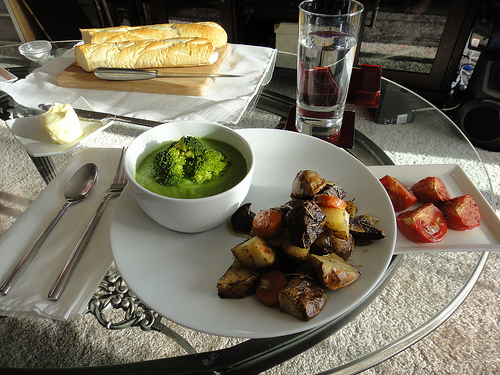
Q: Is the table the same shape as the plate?
A: Yes, both the table and the plate are round.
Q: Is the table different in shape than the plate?
A: No, both the table and the plate are round.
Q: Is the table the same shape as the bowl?
A: Yes, both the table and the bowl are round.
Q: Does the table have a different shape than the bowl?
A: No, both the table and the bowl are round.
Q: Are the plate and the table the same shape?
A: Yes, both the plate and the table are round.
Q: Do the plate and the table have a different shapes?
A: No, both the plate and the table are round.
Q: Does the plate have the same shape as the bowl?
A: Yes, both the plate and the bowl are round.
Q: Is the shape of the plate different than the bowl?
A: No, both the plate and the bowl are round.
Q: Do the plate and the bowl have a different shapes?
A: No, both the plate and the bowl are round.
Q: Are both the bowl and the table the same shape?
A: Yes, both the bowl and the table are round.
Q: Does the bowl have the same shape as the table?
A: Yes, both the bowl and the table are round.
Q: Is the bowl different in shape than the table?
A: No, both the bowl and the table are round.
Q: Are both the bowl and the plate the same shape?
A: Yes, both the bowl and the plate are round.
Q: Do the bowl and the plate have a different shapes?
A: No, both the bowl and the plate are round.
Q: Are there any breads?
A: Yes, there is a bread.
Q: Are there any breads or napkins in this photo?
A: Yes, there is a bread.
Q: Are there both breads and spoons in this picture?
A: Yes, there are both a bread and a spoon.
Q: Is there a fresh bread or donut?
A: Yes, there is a fresh bread.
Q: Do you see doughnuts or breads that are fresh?
A: Yes, the bread is fresh.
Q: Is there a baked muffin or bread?
A: Yes, there is a baked bread.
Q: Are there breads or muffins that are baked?
A: Yes, the bread is baked.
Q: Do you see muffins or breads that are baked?
A: Yes, the bread is baked.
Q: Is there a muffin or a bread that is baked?
A: Yes, the bread is baked.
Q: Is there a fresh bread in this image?
A: Yes, there is a fresh bread.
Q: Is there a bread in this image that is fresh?
A: Yes, there is a bread that is fresh.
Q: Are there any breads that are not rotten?
A: Yes, there is a fresh bread.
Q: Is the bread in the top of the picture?
A: Yes, the bread is in the top of the image.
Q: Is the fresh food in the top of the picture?
A: Yes, the bread is in the top of the image.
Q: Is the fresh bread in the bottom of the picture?
A: No, the bread is in the top of the image.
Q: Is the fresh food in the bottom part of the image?
A: No, the bread is in the top of the image.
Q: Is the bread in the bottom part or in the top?
A: The bread is in the top of the image.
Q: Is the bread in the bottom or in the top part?
A: The bread is in the top of the image.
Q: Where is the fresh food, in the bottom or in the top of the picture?
A: The bread is in the top of the image.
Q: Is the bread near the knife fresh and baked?
A: Yes, the bread is fresh and baked.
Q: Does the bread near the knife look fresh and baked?
A: Yes, the bread is fresh and baked.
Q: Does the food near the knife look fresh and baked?
A: Yes, the bread is fresh and baked.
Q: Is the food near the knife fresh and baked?
A: Yes, the bread is fresh and baked.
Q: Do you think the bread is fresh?
A: Yes, the bread is fresh.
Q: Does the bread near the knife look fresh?
A: Yes, the bread is fresh.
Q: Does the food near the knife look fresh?
A: Yes, the bread is fresh.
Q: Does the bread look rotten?
A: No, the bread is fresh.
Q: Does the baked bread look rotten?
A: No, the bread is fresh.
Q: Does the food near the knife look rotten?
A: No, the bread is fresh.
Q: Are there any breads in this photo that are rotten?
A: No, there is a bread but it is fresh.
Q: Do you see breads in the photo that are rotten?
A: No, there is a bread but it is fresh.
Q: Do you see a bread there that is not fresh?
A: No, there is a bread but it is fresh.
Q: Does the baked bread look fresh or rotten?
A: The bread is fresh.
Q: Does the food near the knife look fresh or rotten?
A: The bread is fresh.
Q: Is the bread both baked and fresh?
A: Yes, the bread is baked and fresh.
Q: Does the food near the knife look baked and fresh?
A: Yes, the bread is baked and fresh.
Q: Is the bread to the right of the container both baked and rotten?
A: No, the bread is baked but fresh.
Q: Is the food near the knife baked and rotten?
A: No, the bread is baked but fresh.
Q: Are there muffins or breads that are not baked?
A: No, there is a bread but it is baked.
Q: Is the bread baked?
A: Yes, the bread is baked.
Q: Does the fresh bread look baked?
A: Yes, the bread is baked.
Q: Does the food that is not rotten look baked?
A: Yes, the bread is baked.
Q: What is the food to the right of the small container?
A: The food is a bread.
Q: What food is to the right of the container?
A: The food is a bread.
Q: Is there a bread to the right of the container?
A: Yes, there is a bread to the right of the container.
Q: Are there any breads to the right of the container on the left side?
A: Yes, there is a bread to the right of the container.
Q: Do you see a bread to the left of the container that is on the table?
A: No, the bread is to the right of the container.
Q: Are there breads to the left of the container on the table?
A: No, the bread is to the right of the container.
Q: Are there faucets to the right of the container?
A: No, there is a bread to the right of the container.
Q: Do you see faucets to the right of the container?
A: No, there is a bread to the right of the container.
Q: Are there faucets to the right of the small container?
A: No, there is a bread to the right of the container.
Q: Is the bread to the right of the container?
A: Yes, the bread is to the right of the container.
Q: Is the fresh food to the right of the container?
A: Yes, the bread is to the right of the container.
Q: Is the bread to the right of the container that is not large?
A: Yes, the bread is to the right of the container.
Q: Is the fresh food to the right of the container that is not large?
A: Yes, the bread is to the right of the container.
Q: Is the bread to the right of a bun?
A: No, the bread is to the right of the container.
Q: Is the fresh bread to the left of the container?
A: No, the bread is to the right of the container.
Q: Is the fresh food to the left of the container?
A: No, the bread is to the right of the container.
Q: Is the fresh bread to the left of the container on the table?
A: No, the bread is to the right of the container.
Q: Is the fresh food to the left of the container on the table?
A: No, the bread is to the right of the container.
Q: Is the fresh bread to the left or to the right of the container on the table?
A: The bread is to the right of the container.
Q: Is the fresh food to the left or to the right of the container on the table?
A: The bread is to the right of the container.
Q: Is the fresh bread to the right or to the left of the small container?
A: The bread is to the right of the container.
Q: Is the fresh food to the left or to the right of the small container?
A: The bread is to the right of the container.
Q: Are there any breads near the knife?
A: Yes, there is a bread near the knife.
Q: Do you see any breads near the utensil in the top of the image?
A: Yes, there is a bread near the knife.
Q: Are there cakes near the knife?
A: No, there is a bread near the knife.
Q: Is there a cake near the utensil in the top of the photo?
A: No, there is a bread near the knife.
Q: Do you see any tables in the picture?
A: Yes, there is a table.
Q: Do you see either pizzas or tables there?
A: Yes, there is a table.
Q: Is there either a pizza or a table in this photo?
A: Yes, there is a table.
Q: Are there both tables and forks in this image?
A: Yes, there are both a table and a fork.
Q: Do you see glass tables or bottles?
A: Yes, there is a glass table.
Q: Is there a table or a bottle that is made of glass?
A: Yes, the table is made of glass.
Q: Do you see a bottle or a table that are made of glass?
A: Yes, the table is made of glass.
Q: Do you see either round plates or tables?
A: Yes, there is a round table.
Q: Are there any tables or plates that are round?
A: Yes, the table is round.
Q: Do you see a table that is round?
A: Yes, there is a round table.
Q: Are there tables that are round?
A: Yes, there is a table that is round.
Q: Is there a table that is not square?
A: Yes, there is a round table.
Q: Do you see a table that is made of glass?
A: Yes, there is a table that is made of glass.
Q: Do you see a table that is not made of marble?
A: Yes, there is a table that is made of glass.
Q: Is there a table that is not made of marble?
A: Yes, there is a table that is made of glass.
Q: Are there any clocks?
A: No, there are no clocks.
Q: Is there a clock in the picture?
A: No, there are no clocks.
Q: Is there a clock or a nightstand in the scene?
A: No, there are no clocks or nightstands.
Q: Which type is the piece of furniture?
A: The piece of furniture is a table.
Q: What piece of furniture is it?
A: The piece of furniture is a table.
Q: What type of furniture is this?
A: This is a table.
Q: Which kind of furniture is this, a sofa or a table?
A: This is a table.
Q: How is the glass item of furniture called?
A: The piece of furniture is a table.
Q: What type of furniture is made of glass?
A: The furniture is a table.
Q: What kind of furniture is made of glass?
A: The furniture is a table.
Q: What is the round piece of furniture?
A: The piece of furniture is a table.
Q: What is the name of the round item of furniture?
A: The piece of furniture is a table.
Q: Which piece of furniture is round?
A: The piece of furniture is a table.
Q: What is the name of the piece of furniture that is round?
A: The piece of furniture is a table.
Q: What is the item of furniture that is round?
A: The piece of furniture is a table.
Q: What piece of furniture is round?
A: The piece of furniture is a table.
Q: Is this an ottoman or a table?
A: This is a table.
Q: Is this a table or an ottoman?
A: This is a table.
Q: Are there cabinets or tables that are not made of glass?
A: No, there is a table but it is made of glass.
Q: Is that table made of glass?
A: Yes, the table is made of glass.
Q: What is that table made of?
A: The table is made of glass.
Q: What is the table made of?
A: The table is made of glass.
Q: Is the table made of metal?
A: No, the table is made of glass.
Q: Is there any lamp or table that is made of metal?
A: No, there is a table but it is made of glass.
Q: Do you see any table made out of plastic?
A: No, there is a table but it is made of glass.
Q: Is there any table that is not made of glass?
A: No, there is a table but it is made of glass.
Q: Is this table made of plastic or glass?
A: The table is made of glass.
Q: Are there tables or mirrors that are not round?
A: No, there is a table but it is round.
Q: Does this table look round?
A: Yes, the table is round.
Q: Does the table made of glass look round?
A: Yes, the table is round.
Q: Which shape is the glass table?
A: The table is round.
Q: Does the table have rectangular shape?
A: No, the table is round.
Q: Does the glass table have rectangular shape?
A: No, the table is round.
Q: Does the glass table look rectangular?
A: No, the table is round.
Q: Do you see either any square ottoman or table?
A: No, there is a table but it is round.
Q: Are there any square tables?
A: No, there is a table but it is round.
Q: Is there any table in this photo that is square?
A: No, there is a table but it is round.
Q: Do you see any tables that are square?
A: No, there is a table but it is round.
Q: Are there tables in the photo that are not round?
A: No, there is a table but it is round.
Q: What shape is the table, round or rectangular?
A: The table is round.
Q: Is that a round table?
A: Yes, that is a round table.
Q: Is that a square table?
A: No, that is a round table.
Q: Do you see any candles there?
A: No, there are no candles.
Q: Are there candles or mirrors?
A: No, there are no candles or mirrors.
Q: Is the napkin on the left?
A: Yes, the napkin is on the left of the image.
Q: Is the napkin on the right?
A: No, the napkin is on the left of the image.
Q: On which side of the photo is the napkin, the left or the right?
A: The napkin is on the left of the image.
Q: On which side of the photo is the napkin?
A: The napkin is on the left of the image.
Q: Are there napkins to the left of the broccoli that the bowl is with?
A: Yes, there is a napkin to the left of the broccoli.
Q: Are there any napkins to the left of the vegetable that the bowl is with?
A: Yes, there is a napkin to the left of the broccoli.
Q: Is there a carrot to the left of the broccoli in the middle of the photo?
A: No, there is a napkin to the left of the broccoli.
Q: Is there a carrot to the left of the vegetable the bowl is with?
A: No, there is a napkin to the left of the broccoli.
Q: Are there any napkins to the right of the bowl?
A: No, the napkin is to the left of the bowl.